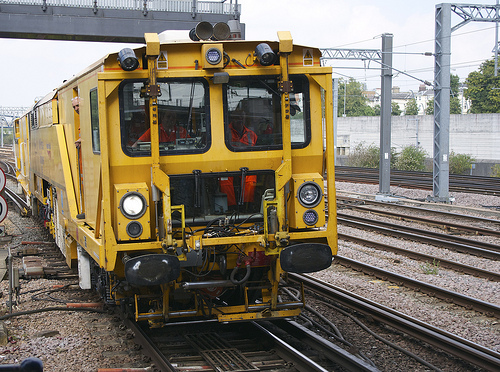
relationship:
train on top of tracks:
[7, 14, 349, 336] [205, 267, 497, 370]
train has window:
[7, 14, 349, 336] [115, 79, 213, 156]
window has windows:
[115, 79, 213, 156] [236, 82, 382, 189]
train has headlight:
[7, 14, 349, 336] [301, 182, 319, 207]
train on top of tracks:
[7, 14, 349, 336] [373, 197, 470, 344]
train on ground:
[7, 14, 349, 336] [6, 317, 117, 367]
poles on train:
[370, 21, 462, 208] [7, 14, 349, 336]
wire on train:
[0, 254, 109, 336] [7, 14, 349, 336]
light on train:
[299, 181, 319, 209] [7, 14, 349, 336]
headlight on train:
[118, 49, 141, 70] [7, 14, 349, 336]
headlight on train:
[301, 182, 319, 207] [7, 14, 349, 336]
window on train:
[219, 82, 313, 154] [7, 14, 349, 336]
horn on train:
[191, 19, 230, 42] [7, 14, 349, 336]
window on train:
[87, 85, 104, 156] [7, 14, 349, 336]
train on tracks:
[7, 14, 349, 336] [2, 167, 490, 369]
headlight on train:
[115, 190, 147, 225] [7, 14, 349, 336]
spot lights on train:
[118, 45, 141, 67] [7, 14, 349, 336]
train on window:
[7, 14, 349, 336] [115, 79, 213, 156]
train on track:
[7, 14, 349, 336] [146, 326, 347, 370]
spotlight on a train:
[254, 38, 279, 68] [7, 14, 349, 336]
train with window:
[7, 14, 349, 336] [126, 78, 216, 156]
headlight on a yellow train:
[115, 190, 147, 225] [13, 30, 353, 350]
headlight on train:
[115, 190, 147, 225] [12, 32, 377, 355]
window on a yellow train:
[115, 79, 213, 156] [13, 30, 353, 350]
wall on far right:
[344, 116, 499, 166] [389, 75, 483, 186]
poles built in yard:
[370, 21, 400, 202] [331, 136, 493, 183]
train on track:
[7, 14, 349, 336] [129, 324, 329, 369]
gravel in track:
[353, 172, 496, 320] [223, 136, 493, 366]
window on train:
[115, 79, 213, 156] [122, 70, 230, 158]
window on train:
[159, 167, 279, 234] [7, 14, 349, 336]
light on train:
[118, 190, 148, 220] [23, 35, 370, 310]